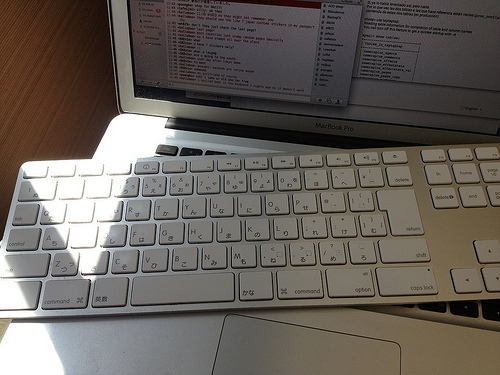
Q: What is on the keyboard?
A: Letters.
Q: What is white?
A: Computer.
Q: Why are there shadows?
A: Sun.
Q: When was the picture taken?
A: Daytime.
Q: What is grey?
A: Shadow.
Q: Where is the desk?
A: Under the computer.